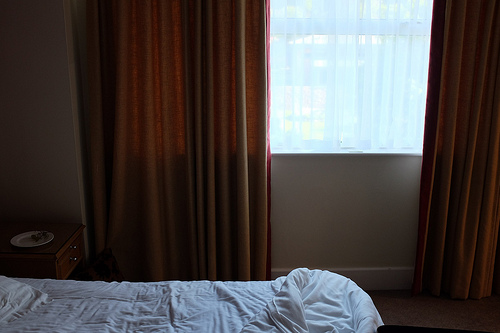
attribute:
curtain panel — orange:
[418, 1, 498, 301]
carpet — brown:
[380, 287, 499, 323]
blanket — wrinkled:
[10, 258, 422, 331]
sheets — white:
[18, 270, 371, 331]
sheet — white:
[242, 266, 383, 331]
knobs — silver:
[71, 239, 81, 264]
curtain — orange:
[25, 0, 272, 272]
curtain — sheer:
[424, 1, 496, 299]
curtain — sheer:
[80, 3, 269, 276]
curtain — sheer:
[268, 2, 428, 154]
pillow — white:
[0, 266, 46, 331]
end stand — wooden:
[1, 220, 91, 285]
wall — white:
[255, 174, 422, 214]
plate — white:
[10, 227, 67, 262]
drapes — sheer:
[73, 3, 275, 284]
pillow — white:
[274, 263, 389, 332]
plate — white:
[4, 224, 57, 252]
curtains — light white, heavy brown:
[71, 0, 485, 302]